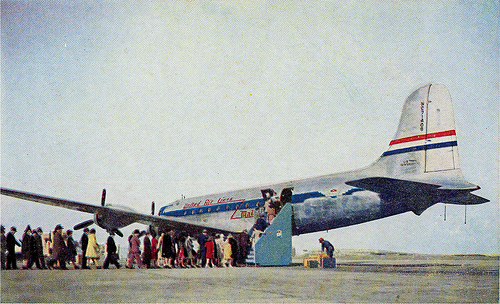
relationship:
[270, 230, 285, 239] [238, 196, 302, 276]
sign on stair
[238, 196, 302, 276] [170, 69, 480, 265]
stair beside plane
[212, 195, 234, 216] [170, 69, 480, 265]
window on plane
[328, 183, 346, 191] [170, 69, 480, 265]
red on plane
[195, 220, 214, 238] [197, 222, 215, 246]
man on tarmac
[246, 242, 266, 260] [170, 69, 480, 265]
step to plane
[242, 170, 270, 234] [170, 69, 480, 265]
passeners on plane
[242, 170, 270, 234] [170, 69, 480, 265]
passeners loading plane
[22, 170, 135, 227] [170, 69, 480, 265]
wing of plane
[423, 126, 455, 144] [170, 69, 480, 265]
tail of plane